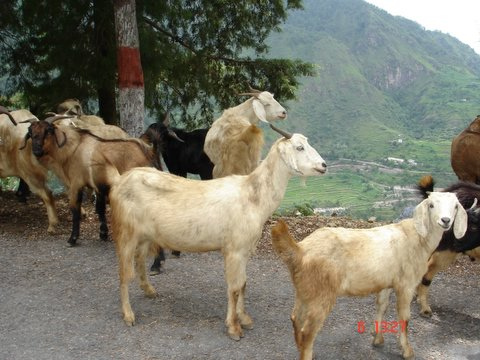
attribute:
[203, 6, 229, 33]
leaf — green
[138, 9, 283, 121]
plant — green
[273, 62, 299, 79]
leaf — green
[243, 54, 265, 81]
leaf — green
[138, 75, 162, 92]
leaf — green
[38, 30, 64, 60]
leaf — green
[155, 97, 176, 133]
leaf — green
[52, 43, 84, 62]
leaf — green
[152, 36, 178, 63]
leaf — green